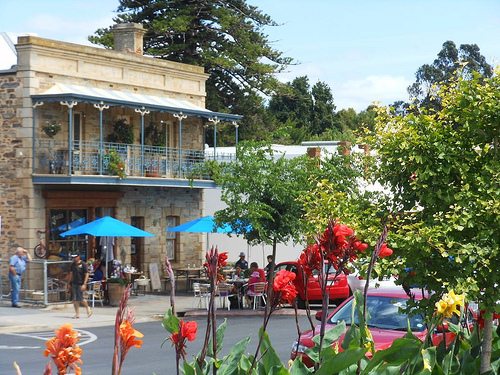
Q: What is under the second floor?
A: Umbrellas.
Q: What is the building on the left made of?
A: Stone.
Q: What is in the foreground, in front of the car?
A: Flowers.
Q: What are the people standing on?
A: Sidewalk.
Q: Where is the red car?
A: Across from the building.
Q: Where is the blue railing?
A: Over the umbrellas.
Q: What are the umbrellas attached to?
A: Tables.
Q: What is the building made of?
A: Brick.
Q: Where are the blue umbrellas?
A: On the patio.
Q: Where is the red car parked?
A: In front of the building.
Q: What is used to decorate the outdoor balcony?
A: Plants.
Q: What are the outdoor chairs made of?
A: Metal.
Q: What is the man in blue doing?
A: Leaning on the fence.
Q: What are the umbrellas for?
A: To protect from the weather.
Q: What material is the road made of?
A: Asphalt.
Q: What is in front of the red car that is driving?
A: Plants.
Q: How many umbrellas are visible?
A: Two.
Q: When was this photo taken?
A: Daytime.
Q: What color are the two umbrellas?
A: Blue.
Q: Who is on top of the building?
A: No one.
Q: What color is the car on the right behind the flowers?
A: Red.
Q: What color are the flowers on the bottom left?
A: Orange.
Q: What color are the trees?
A: Green.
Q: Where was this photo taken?
A: At a cafe.